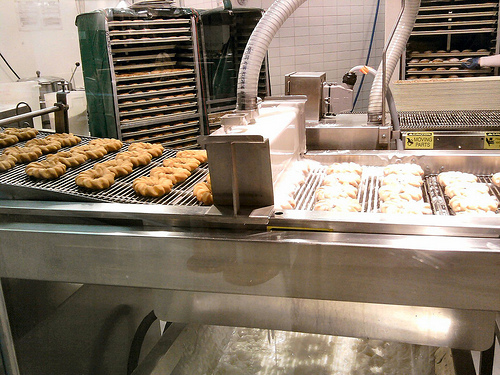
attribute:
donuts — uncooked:
[294, 156, 481, 212]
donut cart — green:
[78, 9, 221, 158]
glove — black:
[459, 52, 480, 72]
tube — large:
[232, 1, 308, 119]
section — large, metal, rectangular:
[209, 95, 312, 218]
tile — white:
[305, 36, 326, 46]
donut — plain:
[130, 177, 174, 197]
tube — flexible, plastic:
[234, 0, 301, 107]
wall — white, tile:
[268, 4, 386, 119]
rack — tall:
[79, 8, 217, 163]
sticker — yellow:
[403, 130, 435, 150]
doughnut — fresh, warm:
[105, 157, 131, 171]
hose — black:
[132, 311, 158, 335]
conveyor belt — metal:
[2, 143, 473, 179]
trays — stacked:
[115, 73, 193, 116]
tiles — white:
[324, 22, 355, 42]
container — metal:
[36, 73, 63, 90]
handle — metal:
[69, 63, 80, 84]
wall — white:
[268, 25, 352, 70]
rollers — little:
[52, 173, 72, 193]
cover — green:
[79, 39, 108, 105]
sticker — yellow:
[406, 131, 439, 150]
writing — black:
[403, 132, 420, 144]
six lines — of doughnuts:
[3, 126, 223, 200]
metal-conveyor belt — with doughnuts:
[0, 120, 485, 228]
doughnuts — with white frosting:
[406, 42, 482, 83]